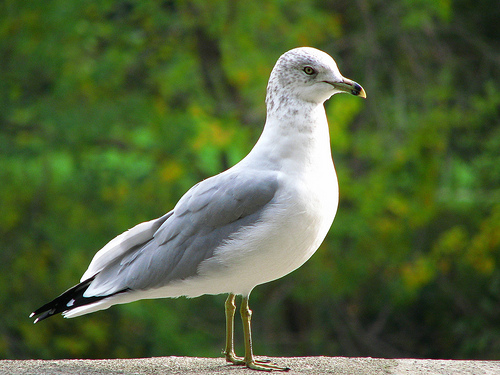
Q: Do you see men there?
A: No, there are no men.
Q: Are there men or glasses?
A: No, there are no men or glasses.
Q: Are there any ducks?
A: No, there are no ducks.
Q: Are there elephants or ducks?
A: No, there are no ducks or elephants.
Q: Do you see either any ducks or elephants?
A: No, there are no ducks or elephants.